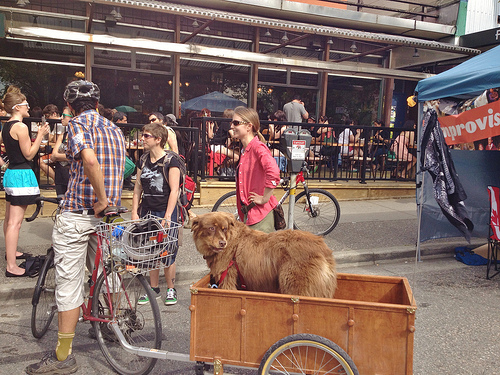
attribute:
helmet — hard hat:
[62, 80, 102, 104]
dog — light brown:
[189, 210, 337, 299]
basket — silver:
[97, 214, 182, 280]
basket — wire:
[85, 221, 146, 269]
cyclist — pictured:
[24, 79, 124, 372]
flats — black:
[6, 252, 32, 262]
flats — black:
[4, 261, 32, 278]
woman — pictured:
[228, 103, 280, 233]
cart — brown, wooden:
[190, 258, 425, 371]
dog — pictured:
[186, 201, 342, 310]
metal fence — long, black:
[0, 112, 413, 201]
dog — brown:
[185, 207, 359, 294]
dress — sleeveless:
[0, 114, 48, 234]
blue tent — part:
[405, 37, 498, 245]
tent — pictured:
[360, 61, 499, 271]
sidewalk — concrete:
[311, 201, 461, 269]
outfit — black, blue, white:
[1, 118, 41, 204]